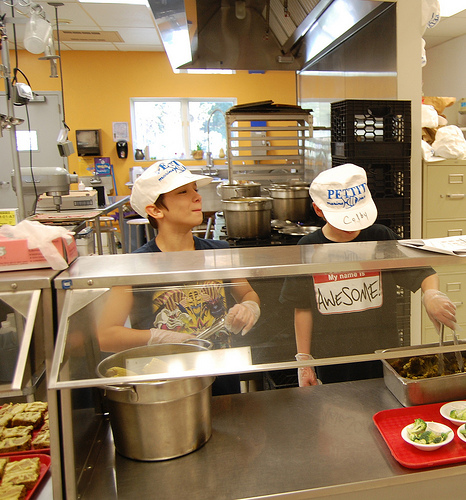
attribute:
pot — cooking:
[219, 195, 273, 234]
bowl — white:
[400, 414, 455, 452]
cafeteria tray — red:
[370, 400, 465, 470]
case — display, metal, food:
[54, 246, 465, 497]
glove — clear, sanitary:
[224, 297, 261, 337]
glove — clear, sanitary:
[145, 328, 200, 345]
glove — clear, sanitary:
[424, 283, 456, 332]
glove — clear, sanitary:
[292, 353, 315, 388]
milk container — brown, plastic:
[329, 97, 412, 160]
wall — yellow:
[0, 48, 304, 205]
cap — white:
[124, 155, 211, 217]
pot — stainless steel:
[95, 336, 214, 461]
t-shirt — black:
[277, 223, 434, 386]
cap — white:
[284, 168, 369, 227]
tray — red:
[379, 408, 464, 458]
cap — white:
[288, 151, 393, 234]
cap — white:
[117, 150, 218, 221]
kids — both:
[116, 155, 428, 316]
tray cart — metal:
[222, 101, 317, 192]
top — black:
[278, 223, 430, 385]